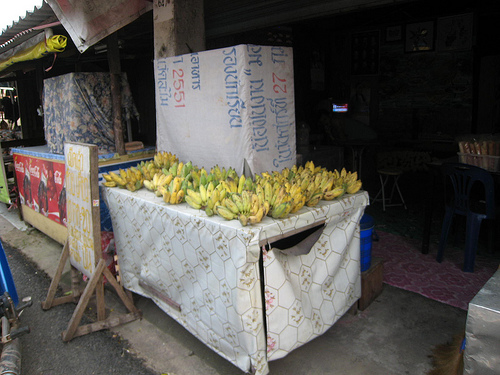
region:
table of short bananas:
[85, 138, 408, 295]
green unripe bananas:
[191, 171, 219, 188]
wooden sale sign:
[23, 122, 134, 334]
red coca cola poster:
[8, 146, 64, 230]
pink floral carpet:
[383, 221, 470, 321]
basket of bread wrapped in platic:
[451, 122, 491, 182]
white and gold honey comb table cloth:
[105, 191, 275, 342]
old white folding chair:
[371, 148, 408, 205]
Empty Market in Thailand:
[8, 80, 378, 333]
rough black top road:
[19, 262, 124, 368]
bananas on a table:
[118, 46, 387, 282]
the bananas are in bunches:
[98, 98, 378, 243]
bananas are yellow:
[128, 141, 412, 276]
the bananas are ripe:
[99, 105, 401, 274]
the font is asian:
[208, 68, 295, 149]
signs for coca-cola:
[13, 121, 78, 218]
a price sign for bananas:
[37, 130, 145, 330]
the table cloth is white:
[153, 232, 333, 333]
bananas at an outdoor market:
[22, 10, 453, 373]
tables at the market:
[34, 87, 353, 274]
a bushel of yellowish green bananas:
[195, 172, 272, 225]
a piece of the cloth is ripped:
[247, 217, 349, 256]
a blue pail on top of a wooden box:
[341, 208, 391, 303]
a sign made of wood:
[34, 140, 135, 339]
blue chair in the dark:
[386, 144, 487, 258]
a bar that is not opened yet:
[271, 3, 496, 301]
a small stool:
[359, 157, 407, 222]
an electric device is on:
[302, 88, 364, 125]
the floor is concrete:
[117, 286, 234, 366]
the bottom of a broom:
[422, 324, 471, 373]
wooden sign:
[38, 146, 136, 347]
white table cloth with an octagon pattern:
[111, 187, 392, 369]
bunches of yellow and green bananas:
[192, 171, 309, 225]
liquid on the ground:
[423, 326, 468, 373]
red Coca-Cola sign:
[13, 153, 89, 225]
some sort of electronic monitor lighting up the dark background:
[331, 101, 352, 115]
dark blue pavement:
[3, 251, 134, 373]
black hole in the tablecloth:
[268, 223, 332, 269]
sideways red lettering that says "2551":
[170, 66, 187, 113]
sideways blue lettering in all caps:
[221, 52, 248, 131]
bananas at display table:
[95, 130, 372, 348]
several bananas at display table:
[75, 141, 383, 332]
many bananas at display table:
[75, 131, 400, 348]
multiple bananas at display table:
[80, 110, 394, 352]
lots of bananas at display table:
[81, 98, 394, 357]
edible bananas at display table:
[73, 76, 398, 348]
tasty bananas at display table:
[73, 86, 398, 346]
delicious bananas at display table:
[87, 88, 396, 353]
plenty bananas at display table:
[90, 95, 389, 322]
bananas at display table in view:
[74, 99, 405, 357]